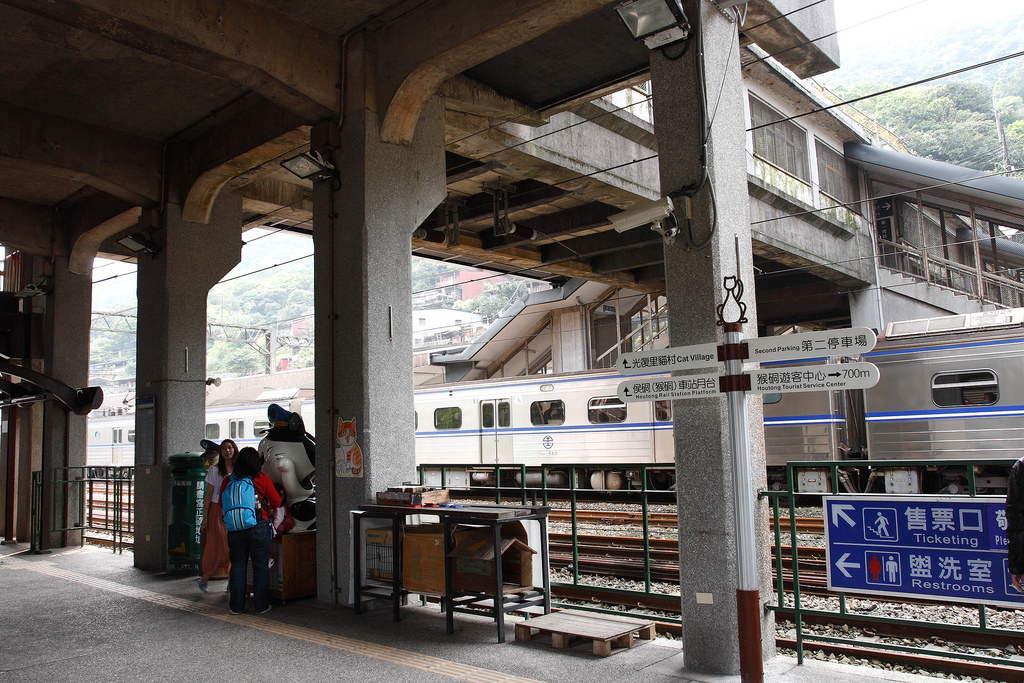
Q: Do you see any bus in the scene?
A: No, there are no buses.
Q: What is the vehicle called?
A: The vehicle is a car.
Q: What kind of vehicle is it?
A: The vehicle is a car.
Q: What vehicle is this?
A: This is a car.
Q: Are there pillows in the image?
A: No, there are no pillows.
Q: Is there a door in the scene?
A: Yes, there is a door.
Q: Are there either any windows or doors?
A: Yes, there is a door.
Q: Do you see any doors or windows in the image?
A: Yes, there is a door.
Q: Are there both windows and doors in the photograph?
A: Yes, there are both a door and windows.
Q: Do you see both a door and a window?
A: Yes, there are both a door and a window.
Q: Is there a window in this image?
A: Yes, there is a window.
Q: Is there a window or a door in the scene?
A: Yes, there is a window.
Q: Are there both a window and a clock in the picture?
A: No, there is a window but no clocks.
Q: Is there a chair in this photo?
A: No, there are no chairs.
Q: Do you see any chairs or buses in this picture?
A: No, there are no chairs or buses.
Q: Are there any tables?
A: Yes, there is a table.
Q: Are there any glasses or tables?
A: Yes, there is a table.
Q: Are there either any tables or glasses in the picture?
A: Yes, there is a table.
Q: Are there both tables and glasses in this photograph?
A: No, there is a table but no glasses.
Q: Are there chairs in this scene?
A: No, there are no chairs.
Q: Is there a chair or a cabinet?
A: No, there are no chairs or cabinets.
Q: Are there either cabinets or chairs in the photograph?
A: No, there are no chairs or cabinets.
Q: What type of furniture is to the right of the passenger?
A: The piece of furniture is a table.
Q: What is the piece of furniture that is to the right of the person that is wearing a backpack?
A: The piece of furniture is a table.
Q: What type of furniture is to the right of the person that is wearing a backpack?
A: The piece of furniture is a table.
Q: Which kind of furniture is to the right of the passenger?
A: The piece of furniture is a table.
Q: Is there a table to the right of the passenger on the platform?
A: Yes, there is a table to the right of the passenger.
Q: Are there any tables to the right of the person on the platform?
A: Yes, there is a table to the right of the passenger.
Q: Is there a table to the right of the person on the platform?
A: Yes, there is a table to the right of the passenger.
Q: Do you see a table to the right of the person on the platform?
A: Yes, there is a table to the right of the passenger.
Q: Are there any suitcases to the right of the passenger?
A: No, there is a table to the right of the passenger.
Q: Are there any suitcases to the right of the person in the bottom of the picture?
A: No, there is a table to the right of the passenger.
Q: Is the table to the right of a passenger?
A: Yes, the table is to the right of a passenger.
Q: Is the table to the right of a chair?
A: No, the table is to the right of a passenger.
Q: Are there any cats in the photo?
A: Yes, there is a cat.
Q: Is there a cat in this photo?
A: Yes, there is a cat.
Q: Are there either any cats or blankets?
A: Yes, there is a cat.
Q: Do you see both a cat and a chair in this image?
A: No, there is a cat but no chairs.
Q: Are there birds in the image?
A: No, there are no birds.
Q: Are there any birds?
A: No, there are no birds.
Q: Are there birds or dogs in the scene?
A: No, there are no birds or dogs.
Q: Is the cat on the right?
A: Yes, the cat is on the right of the image.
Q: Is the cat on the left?
A: No, the cat is on the right of the image.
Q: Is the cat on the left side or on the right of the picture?
A: The cat is on the right of the image.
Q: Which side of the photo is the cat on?
A: The cat is on the right of the image.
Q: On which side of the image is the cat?
A: The cat is on the right of the image.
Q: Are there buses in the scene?
A: No, there are no buses.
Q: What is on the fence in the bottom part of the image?
A: The sign is on the fence.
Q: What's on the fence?
A: The sign is on the fence.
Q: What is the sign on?
A: The sign is on the fence.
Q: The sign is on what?
A: The sign is on the fence.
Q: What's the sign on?
A: The sign is on the fence.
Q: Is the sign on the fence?
A: Yes, the sign is on the fence.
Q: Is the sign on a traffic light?
A: No, the sign is on the fence.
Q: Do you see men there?
A: No, there are no men.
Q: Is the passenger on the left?
A: Yes, the passenger is on the left of the image.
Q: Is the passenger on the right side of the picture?
A: No, the passenger is on the left of the image.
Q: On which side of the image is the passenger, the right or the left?
A: The passenger is on the left of the image.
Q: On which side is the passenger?
A: The passenger is on the left of the image.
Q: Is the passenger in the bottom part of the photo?
A: Yes, the passenger is in the bottom of the image.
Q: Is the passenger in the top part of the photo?
A: No, the passenger is in the bottom of the image.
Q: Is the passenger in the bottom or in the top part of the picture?
A: The passenger is in the bottom of the image.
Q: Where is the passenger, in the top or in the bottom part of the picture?
A: The passenger is in the bottom of the image.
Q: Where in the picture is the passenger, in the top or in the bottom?
A: The passenger is in the bottom of the image.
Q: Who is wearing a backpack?
A: The passenger is wearing a backpack.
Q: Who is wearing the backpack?
A: The passenger is wearing a backpack.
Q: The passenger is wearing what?
A: The passenger is wearing a backpack.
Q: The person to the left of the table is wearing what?
A: The passenger is wearing a backpack.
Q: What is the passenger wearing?
A: The passenger is wearing a backpack.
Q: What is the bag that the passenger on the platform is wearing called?
A: The bag is a backpack.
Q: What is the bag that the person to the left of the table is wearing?
A: The bag is a backpack.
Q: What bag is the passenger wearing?
A: The passenger is wearing a backpack.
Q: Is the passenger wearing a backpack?
A: Yes, the passenger is wearing a backpack.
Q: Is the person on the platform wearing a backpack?
A: Yes, the passenger is wearing a backpack.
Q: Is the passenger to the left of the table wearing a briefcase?
A: No, the passenger is wearing a backpack.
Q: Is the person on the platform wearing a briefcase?
A: No, the passenger is wearing a backpack.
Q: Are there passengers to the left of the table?
A: Yes, there is a passenger to the left of the table.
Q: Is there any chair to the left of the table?
A: No, there is a passenger to the left of the table.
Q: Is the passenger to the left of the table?
A: Yes, the passenger is to the left of the table.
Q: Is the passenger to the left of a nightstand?
A: No, the passenger is to the left of the table.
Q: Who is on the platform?
A: The passenger is on the platform.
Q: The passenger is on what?
A: The passenger is on the platform.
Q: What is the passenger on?
A: The passenger is on the platform.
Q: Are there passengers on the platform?
A: Yes, there is a passenger on the platform.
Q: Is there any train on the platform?
A: No, there is a passenger on the platform.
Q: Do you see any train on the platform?
A: No, there is a passenger on the platform.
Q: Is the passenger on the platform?
A: Yes, the passenger is on the platform.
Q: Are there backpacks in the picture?
A: Yes, there is a backpack.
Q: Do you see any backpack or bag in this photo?
A: Yes, there is a backpack.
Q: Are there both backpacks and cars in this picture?
A: Yes, there are both a backpack and a car.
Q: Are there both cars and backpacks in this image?
A: Yes, there are both a backpack and a car.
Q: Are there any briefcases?
A: No, there are no briefcases.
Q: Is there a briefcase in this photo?
A: No, there are no briefcases.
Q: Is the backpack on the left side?
A: Yes, the backpack is on the left of the image.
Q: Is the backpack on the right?
A: No, the backpack is on the left of the image.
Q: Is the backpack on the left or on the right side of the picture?
A: The backpack is on the left of the image.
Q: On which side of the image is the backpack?
A: The backpack is on the left of the image.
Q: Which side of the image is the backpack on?
A: The backpack is on the left of the image.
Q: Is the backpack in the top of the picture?
A: No, the backpack is in the bottom of the image.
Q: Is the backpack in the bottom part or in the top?
A: The backpack is in the bottom of the image.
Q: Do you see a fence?
A: Yes, there is a fence.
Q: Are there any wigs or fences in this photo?
A: Yes, there is a fence.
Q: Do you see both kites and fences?
A: No, there is a fence but no kites.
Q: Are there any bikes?
A: No, there are no bikes.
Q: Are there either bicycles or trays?
A: No, there are no bicycles or trays.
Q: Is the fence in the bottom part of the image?
A: Yes, the fence is in the bottom of the image.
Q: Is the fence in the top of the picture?
A: No, the fence is in the bottom of the image.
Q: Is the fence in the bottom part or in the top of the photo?
A: The fence is in the bottom of the image.